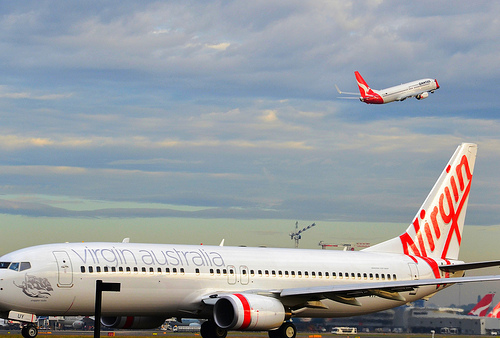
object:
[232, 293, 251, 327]
stripe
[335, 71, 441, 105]
aircraft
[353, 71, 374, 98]
tail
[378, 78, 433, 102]
fuselage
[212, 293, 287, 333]
engine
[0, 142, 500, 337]
virgin aircraft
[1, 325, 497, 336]
ground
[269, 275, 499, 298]
airplane wing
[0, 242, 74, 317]
cockpit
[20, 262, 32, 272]
windows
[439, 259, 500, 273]
horizontal stabilize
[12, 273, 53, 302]
logo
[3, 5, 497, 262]
sky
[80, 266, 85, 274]
windows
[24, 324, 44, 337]
front wheel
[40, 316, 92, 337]
open space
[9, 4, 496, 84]
clouds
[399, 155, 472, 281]
virgin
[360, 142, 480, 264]
tail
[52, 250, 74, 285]
door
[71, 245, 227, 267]
virgin australia log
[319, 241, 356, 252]
crane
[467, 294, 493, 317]
tails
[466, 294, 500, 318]
red planes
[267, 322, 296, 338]
tires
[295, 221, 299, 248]
post